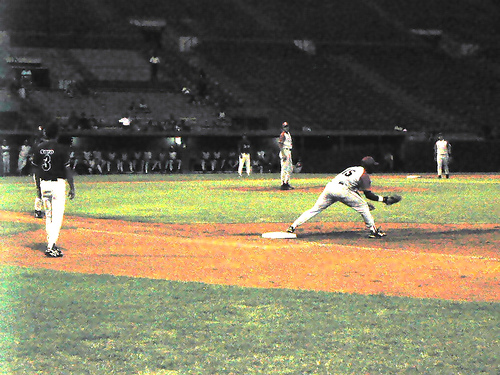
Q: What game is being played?
A: Baseball.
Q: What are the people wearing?
A: Uniforms.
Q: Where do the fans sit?
A: Fan stands.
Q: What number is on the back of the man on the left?
A: 3.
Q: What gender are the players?
A: Male.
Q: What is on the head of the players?
A: Baseball caps.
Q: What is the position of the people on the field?
A: Standing.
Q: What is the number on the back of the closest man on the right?
A: 15.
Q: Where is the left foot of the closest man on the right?
A: On a base.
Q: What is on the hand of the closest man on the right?
A: Ball glove.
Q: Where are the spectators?
A: In the stands.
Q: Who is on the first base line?
A: The player with the #3.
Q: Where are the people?
A: In the stands.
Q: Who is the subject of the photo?
A: The players.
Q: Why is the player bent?
A: Playing baseball.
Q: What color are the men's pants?
A: White.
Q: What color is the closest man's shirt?
A: Black.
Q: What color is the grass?
A: Green.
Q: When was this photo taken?
A: At night.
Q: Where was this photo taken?
A: At a baseball field.